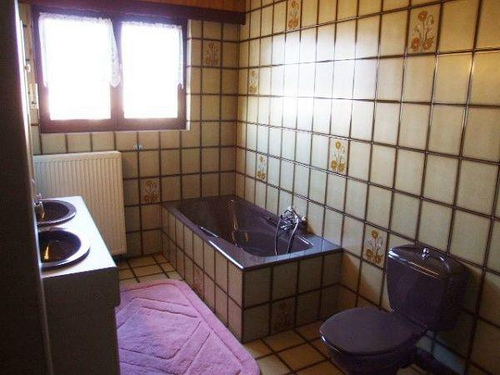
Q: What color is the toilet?
A: Brown.